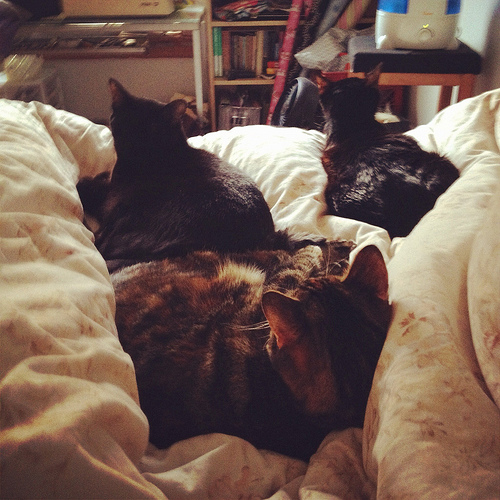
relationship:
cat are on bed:
[74, 73, 291, 261] [1, 89, 494, 498]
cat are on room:
[74, 73, 291, 261] [1, 89, 494, 499]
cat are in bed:
[74, 73, 291, 261] [1, 89, 494, 498]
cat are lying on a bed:
[74, 73, 291, 261] [1, 89, 494, 498]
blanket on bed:
[2, 90, 497, 494] [1, 89, 494, 498]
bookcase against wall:
[202, 2, 297, 126] [1, 14, 201, 121]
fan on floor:
[272, 67, 319, 127] [88, 112, 123, 139]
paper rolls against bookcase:
[295, 17, 358, 76] [201, 1, 331, 123]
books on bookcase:
[212, 32, 281, 76] [202, 2, 297, 126]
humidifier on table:
[374, 13, 456, 47] [348, 34, 480, 111]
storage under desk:
[0, 50, 71, 104] [14, 13, 211, 87]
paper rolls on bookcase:
[295, 21, 347, 76] [207, 3, 281, 119]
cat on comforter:
[74, 73, 291, 261] [381, 160, 498, 497]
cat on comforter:
[307, 62, 445, 233] [381, 160, 498, 497]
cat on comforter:
[113, 234, 390, 459] [381, 160, 498, 497]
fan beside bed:
[272, 67, 319, 127] [0, 92, 121, 498]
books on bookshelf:
[230, 37, 266, 78] [198, 1, 290, 128]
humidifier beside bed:
[369, 0, 462, 50] [189, 117, 328, 227]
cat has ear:
[113, 234, 390, 459] [257, 286, 307, 345]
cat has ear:
[113, 234, 390, 459] [345, 239, 389, 305]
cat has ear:
[74, 73, 291, 261] [110, 75, 135, 108]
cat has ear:
[307, 62, 461, 233] [313, 66, 332, 103]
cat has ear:
[307, 62, 461, 233] [365, 63, 388, 91]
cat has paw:
[74, 73, 291, 261] [80, 174, 107, 206]